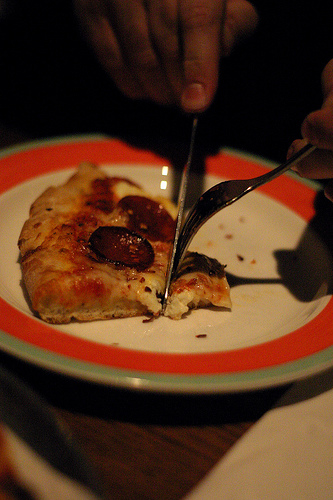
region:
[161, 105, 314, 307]
A fork and knife cutting into pizza.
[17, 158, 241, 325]
Half of a slice of pizza.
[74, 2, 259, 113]
A hand holding a knife.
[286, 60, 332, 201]
A hand holding a fork.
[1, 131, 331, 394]
A plate of pizza.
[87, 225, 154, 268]
A blackened pepperoni on a pizza.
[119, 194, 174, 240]
A pepperoni slice on a pizza.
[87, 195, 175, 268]
Two pepperoni slices on a pizza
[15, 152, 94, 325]
Thin crust of a pizza.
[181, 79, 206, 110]
Fingernail of the index finger.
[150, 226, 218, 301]
knife in fork in a pizza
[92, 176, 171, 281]
pepperoni on a pizza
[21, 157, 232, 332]
piece on pizza on a plate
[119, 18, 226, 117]
person holding a knife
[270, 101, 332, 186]
person holding a fork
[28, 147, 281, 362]
Food on a plate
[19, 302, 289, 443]
plate on the table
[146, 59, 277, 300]
knife and fork in the pizza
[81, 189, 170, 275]
meat on the pizza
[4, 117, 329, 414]
a round plate with food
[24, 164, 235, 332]
a partial slice of pizza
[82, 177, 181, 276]
two pepperoni on pizza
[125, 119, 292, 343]
a fork and knife on pizza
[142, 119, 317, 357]
a sliver fork and knife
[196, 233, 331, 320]
shadow cast by fork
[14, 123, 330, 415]
a white plate with orange and green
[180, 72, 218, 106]
a finger nail on a finger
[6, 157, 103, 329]
the crust of a pizza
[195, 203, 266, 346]
crumbs on the plate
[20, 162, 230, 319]
the pizza is half eaten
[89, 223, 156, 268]
a pepperoni on the pizza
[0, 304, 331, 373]
red stripe on the plate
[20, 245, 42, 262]
burnt sauce on the crust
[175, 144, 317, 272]
a silver fork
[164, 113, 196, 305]
a silver knife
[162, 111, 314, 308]
the silverware is cutting the pizza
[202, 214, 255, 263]
crumbs on the plate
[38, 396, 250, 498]
a wood table top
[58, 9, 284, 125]
this is a hand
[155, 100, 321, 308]
this is a fork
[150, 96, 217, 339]
this is a knife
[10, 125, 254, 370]
a slice of pizza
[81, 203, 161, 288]
a pepperoni on pizza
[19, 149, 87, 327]
golden crust on pizza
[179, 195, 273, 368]
crumbs on dinner plate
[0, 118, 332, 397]
this is a dinner plate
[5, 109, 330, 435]
green trim on plate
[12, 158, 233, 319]
a half eaten slice of pizza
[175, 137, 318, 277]
fork held by hand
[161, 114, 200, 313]
knife is held by hand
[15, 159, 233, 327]
pizza being cut by knife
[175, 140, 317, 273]
fork stuck in pizza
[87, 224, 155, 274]
pepperoni sits on pizza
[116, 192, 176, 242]
pepperoni sits on pizza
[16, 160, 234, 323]
pizza sits on plate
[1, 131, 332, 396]
plate has pizza on it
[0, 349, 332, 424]
shadow cast by plate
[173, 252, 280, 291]
shadow cast by fork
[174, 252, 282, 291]
shadow is cast by fork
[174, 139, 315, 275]
fork is held by human